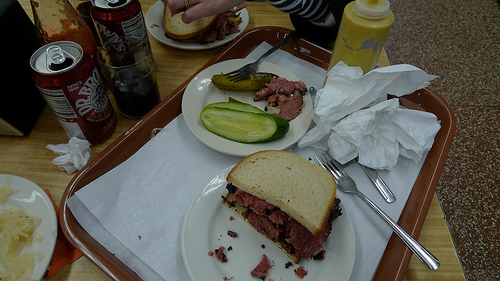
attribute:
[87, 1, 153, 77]
can — drink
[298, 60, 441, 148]
napkin — white, wadded up, crumpled up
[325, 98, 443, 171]
napkin — white, wadded up, crumpled up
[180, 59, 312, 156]
plate — white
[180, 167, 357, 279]
plate — white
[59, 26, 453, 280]
tray — plastic, brown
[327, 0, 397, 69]
bottle — mustard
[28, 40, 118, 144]
can — drink, open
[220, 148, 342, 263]
sandwich — halved, cut 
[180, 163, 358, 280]
dish — white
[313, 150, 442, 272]
fork — silver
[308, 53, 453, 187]
napkin — crumbled, white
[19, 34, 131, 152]
can — open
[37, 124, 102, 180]
paper — white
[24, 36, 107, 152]
soda — open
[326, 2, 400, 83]
bottle — clear, plastic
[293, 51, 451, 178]
napkins — white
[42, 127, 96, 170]
napkins — used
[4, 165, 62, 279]
plate — white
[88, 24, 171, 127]
glass — clear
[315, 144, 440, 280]
fork — silver, metal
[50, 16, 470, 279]
tray — brown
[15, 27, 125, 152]
can — open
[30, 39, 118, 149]
coke — red 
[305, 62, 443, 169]
napkin — white 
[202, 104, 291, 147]
pickle — long 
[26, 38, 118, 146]
soda can — open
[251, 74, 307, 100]
corned beef — stray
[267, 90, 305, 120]
corned beef — stray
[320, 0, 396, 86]
mustard — yellow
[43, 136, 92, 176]
napkin — crumpled up, white